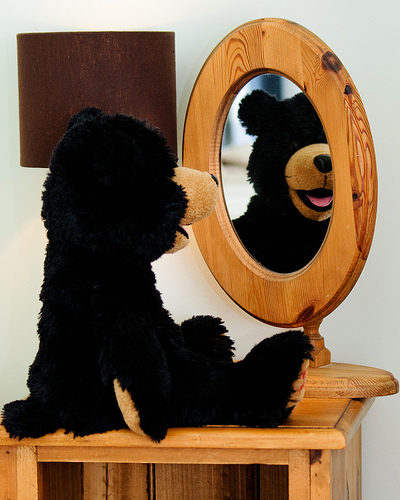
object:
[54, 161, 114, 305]
black color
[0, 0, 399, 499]
wall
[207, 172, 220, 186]
nose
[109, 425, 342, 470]
wood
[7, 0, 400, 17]
clean wall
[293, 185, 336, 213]
mouth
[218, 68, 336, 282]
mirror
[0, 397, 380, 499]
cupboard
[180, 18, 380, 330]
frame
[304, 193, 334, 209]
pink tongue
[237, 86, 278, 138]
ear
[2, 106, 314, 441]
bear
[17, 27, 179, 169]
shade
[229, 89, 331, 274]
bear